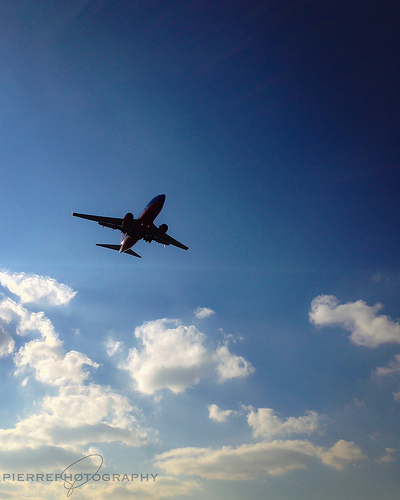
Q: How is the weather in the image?
A: It is sunny.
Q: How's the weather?
A: It is sunny.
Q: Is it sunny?
A: Yes, it is sunny.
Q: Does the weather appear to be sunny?
A: Yes, it is sunny.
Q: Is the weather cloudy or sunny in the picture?
A: It is sunny.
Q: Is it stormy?
A: No, it is sunny.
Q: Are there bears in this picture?
A: No, there are no bears.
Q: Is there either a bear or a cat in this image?
A: No, there are no bears or cats.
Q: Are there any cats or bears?
A: No, there are no bears or cats.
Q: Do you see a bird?
A: No, there are no birds.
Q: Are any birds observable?
A: No, there are no birds.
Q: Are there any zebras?
A: No, there are no zebras.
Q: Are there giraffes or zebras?
A: No, there are no zebras or giraffes.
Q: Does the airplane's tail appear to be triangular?
A: Yes, the tail is triangular.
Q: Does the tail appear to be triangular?
A: Yes, the tail is triangular.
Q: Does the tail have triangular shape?
A: Yes, the tail is triangular.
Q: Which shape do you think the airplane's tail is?
A: The tail is triangular.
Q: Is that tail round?
A: No, the tail is triangular.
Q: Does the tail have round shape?
A: No, the tail is triangular.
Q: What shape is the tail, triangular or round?
A: The tail is triangular.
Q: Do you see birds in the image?
A: No, there are no birds.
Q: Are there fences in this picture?
A: No, there are no fences.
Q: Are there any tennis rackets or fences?
A: No, there are no fences or tennis rackets.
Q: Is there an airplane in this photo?
A: Yes, there is an airplane.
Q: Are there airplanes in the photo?
A: Yes, there is an airplane.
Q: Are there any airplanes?
A: Yes, there is an airplane.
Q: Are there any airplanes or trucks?
A: Yes, there is an airplane.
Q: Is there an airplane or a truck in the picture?
A: Yes, there is an airplane.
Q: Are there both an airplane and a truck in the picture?
A: No, there is an airplane but no trucks.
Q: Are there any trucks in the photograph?
A: No, there are no trucks.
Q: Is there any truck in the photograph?
A: No, there are no trucks.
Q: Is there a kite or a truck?
A: No, there are no trucks or kites.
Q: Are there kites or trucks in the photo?
A: No, there are no trucks or kites.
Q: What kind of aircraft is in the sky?
A: The aircraft is an airplane.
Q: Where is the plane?
A: The plane is in the sky.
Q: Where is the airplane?
A: The plane is in the sky.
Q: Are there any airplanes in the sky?
A: Yes, there is an airplane in the sky.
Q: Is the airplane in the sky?
A: Yes, the airplane is in the sky.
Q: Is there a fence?
A: No, there are no fences.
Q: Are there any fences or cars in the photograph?
A: No, there are no fences or cars.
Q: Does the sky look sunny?
A: Yes, the sky is sunny.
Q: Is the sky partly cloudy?
A: No, the sky is sunny.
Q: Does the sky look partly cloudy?
A: No, the sky is sunny.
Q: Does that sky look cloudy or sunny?
A: The sky is sunny.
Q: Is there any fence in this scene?
A: No, there are no fences.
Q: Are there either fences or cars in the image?
A: No, there are no fences or cars.